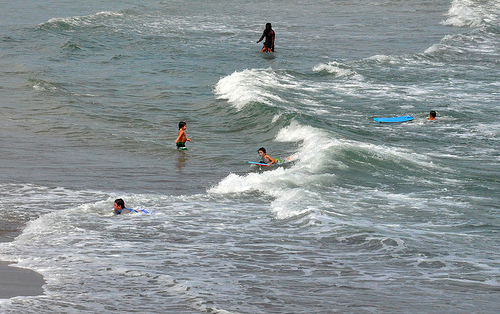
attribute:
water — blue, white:
[22, 63, 90, 130]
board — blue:
[371, 101, 419, 139]